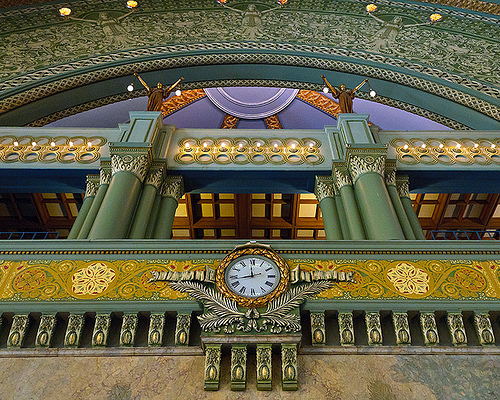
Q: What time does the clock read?
A: 8:59.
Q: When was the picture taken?
A: 8:59.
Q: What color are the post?
A: Green.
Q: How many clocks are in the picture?
A: One.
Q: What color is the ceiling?
A: Purple.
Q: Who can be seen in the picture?
A: No one.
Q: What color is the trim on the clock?
A: Gold.